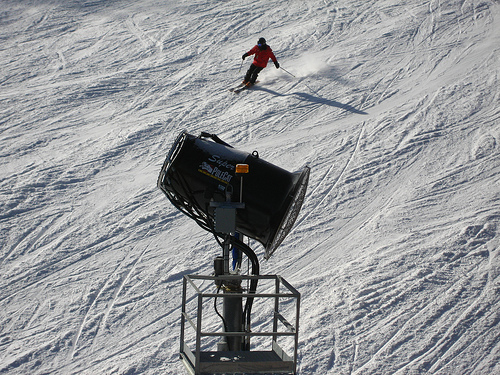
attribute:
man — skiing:
[225, 36, 281, 97]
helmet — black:
[257, 35, 267, 50]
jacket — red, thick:
[249, 49, 276, 66]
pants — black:
[245, 64, 264, 82]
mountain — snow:
[41, 14, 427, 121]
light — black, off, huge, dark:
[163, 136, 316, 258]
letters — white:
[200, 151, 239, 194]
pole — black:
[282, 64, 300, 85]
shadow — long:
[258, 78, 370, 115]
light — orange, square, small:
[235, 159, 248, 177]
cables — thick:
[240, 230, 259, 351]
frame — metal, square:
[172, 264, 309, 367]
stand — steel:
[155, 208, 310, 372]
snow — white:
[43, 21, 107, 79]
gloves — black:
[240, 51, 251, 62]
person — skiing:
[217, 30, 297, 108]